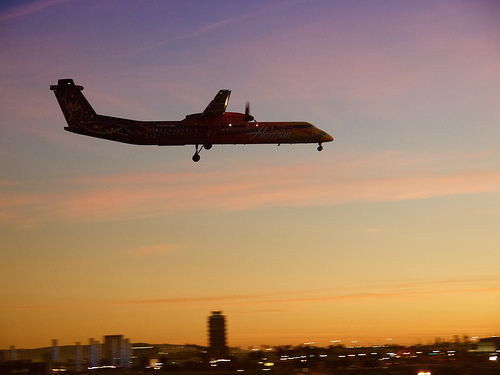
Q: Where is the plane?
A: In the sky.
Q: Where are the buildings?
A: Behind the plane.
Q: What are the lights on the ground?
A: Street lights.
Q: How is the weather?
A: Clear.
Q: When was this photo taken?
A: At dusk.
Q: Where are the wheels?
A: Under the plane.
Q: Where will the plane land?
A: On the ground.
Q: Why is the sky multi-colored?
A: Sun-setting.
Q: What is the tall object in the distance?
A: Skyscraper.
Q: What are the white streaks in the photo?
A: Lights.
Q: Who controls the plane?
A: A pilot.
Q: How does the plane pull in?
A: Gradual decline.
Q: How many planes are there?
A: One.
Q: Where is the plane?
A: In the sky.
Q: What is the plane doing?
A: Flying.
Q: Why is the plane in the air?
A: To reach a destination.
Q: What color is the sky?
A: Orange.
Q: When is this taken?
A: During the dusk.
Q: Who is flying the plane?
A: A pilot.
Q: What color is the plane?
A: White.